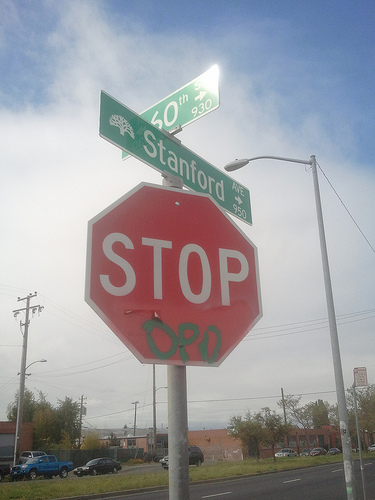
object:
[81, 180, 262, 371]
stop sign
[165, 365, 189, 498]
pole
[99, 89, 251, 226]
sign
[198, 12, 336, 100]
sky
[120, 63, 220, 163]
signs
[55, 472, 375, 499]
street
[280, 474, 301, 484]
line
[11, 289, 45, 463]
post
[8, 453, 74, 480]
truck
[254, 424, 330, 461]
building